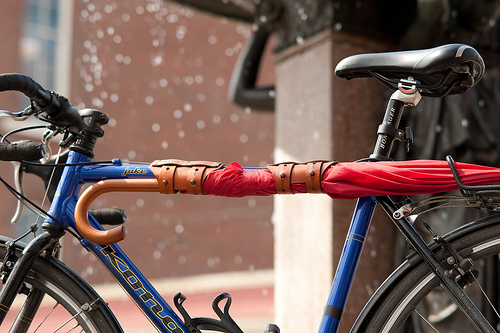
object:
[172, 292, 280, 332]
cupholder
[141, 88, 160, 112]
speck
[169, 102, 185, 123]
speck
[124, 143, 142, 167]
speck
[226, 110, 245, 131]
speck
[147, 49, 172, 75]
speck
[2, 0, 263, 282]
wall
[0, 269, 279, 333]
ground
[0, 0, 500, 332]
outside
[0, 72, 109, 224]
handle bars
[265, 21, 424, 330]
wall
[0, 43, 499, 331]
bicycle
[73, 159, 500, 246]
umbrella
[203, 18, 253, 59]
specks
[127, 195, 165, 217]
specks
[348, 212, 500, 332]
tire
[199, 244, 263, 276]
specks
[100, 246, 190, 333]
black lettering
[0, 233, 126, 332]
tire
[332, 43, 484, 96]
seat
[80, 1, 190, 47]
specks